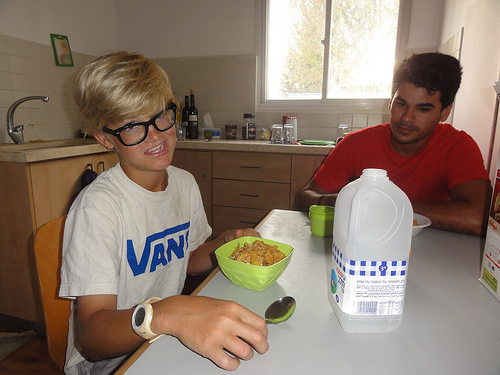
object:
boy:
[78, 64, 211, 364]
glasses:
[105, 99, 183, 143]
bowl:
[244, 264, 266, 285]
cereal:
[242, 247, 268, 256]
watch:
[129, 306, 167, 350]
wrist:
[158, 300, 187, 338]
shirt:
[74, 171, 234, 288]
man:
[324, 48, 470, 248]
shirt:
[339, 112, 469, 210]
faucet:
[1, 72, 54, 172]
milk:
[348, 240, 399, 260]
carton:
[333, 167, 411, 333]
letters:
[122, 238, 192, 274]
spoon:
[250, 302, 295, 327]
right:
[186, 298, 243, 367]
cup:
[311, 207, 337, 235]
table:
[374, 341, 441, 367]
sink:
[10, 125, 57, 173]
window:
[268, 8, 391, 96]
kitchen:
[43, 99, 469, 343]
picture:
[38, 33, 87, 73]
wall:
[162, 39, 232, 55]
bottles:
[178, 94, 204, 137]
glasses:
[278, 121, 318, 156]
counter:
[203, 144, 248, 154]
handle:
[238, 191, 299, 196]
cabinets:
[214, 152, 291, 183]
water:
[35, 120, 67, 153]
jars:
[212, 111, 268, 125]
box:
[203, 132, 236, 140]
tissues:
[199, 106, 211, 125]